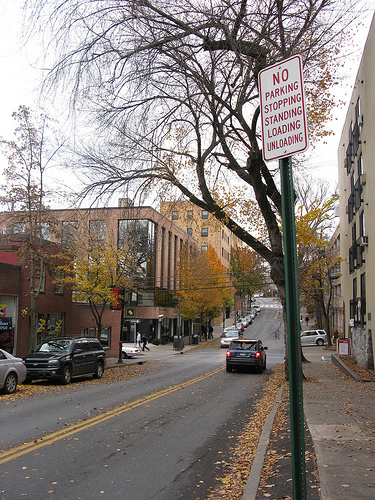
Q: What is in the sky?
A: Clouds.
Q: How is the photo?
A: Clear.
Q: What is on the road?
A: Car.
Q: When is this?
A: Daytime.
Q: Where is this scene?
A: On the street.